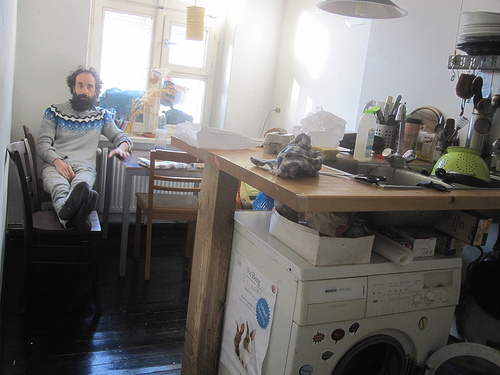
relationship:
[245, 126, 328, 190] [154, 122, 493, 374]
cloth on counter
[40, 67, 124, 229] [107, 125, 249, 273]
man sitting at table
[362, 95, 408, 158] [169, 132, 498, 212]
utensils on counter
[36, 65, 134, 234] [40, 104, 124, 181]
man wearing sweater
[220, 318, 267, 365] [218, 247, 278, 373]
picture on paper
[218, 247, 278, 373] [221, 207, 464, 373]
paper on laundry machine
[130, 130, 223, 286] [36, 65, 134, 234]
chair next to man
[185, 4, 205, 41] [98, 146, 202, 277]
light over table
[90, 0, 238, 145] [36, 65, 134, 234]
window behind man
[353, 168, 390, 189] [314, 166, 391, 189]
handles on scissors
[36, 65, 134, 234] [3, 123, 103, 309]
man on chair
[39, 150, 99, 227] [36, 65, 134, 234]
legs of man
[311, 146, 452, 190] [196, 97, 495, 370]
sink in kitchen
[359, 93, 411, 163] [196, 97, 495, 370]
utensils in kitchen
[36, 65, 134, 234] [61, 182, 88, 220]
man wearing sock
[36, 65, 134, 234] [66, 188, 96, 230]
man wearing sock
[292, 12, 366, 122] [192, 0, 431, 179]
reflection of light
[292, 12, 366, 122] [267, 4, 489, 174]
reflection on wall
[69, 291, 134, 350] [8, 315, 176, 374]
reflection on floor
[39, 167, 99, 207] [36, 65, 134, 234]
legs of man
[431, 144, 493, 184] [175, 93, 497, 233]
colander on table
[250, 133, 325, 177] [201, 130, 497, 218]
cloth on table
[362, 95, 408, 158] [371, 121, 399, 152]
utensils in container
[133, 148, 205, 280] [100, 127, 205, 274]
chair at table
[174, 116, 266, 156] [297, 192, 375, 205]
plastic bag on table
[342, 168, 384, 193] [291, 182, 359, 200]
scissors on table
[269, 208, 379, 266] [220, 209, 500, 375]
box on washer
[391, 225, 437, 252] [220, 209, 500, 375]
box on washer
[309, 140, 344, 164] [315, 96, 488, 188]
sponge on sink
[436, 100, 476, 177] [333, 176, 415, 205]
utensils on table